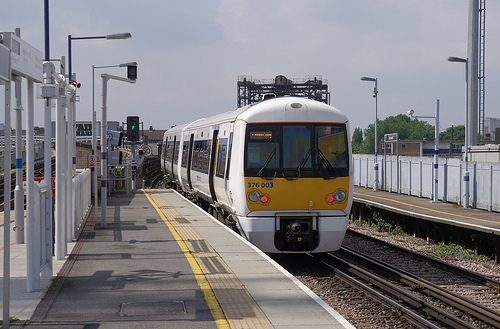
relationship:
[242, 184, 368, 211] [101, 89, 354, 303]
headlights on train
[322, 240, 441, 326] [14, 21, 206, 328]
tracks at station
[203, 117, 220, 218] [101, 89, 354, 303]
door on train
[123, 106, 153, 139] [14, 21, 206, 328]
light at station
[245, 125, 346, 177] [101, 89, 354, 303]
windshield on train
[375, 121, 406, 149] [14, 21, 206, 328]
sign at station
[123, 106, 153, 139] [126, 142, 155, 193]
light on pole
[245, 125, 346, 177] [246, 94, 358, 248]
windows in front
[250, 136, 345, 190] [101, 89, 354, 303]
wipers on train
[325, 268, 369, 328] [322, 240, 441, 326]
gravel between tracks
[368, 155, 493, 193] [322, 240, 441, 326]
fence by tracks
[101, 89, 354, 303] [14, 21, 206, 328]
train at station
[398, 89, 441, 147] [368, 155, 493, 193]
lamp next to fence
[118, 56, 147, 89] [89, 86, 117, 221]
camers on pole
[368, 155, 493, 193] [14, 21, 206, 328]
fence around station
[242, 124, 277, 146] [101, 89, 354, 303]
sign on train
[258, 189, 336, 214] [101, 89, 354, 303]
lights on train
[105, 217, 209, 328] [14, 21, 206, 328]
cement at station